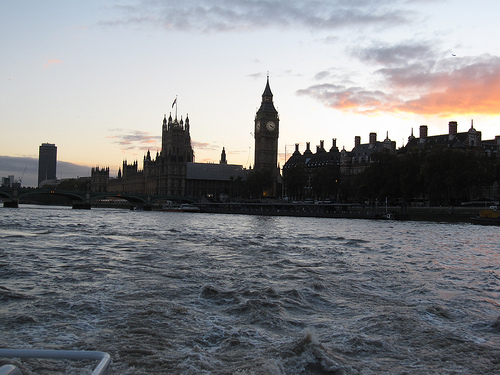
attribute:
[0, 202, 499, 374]
water — calm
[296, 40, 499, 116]
cloud — orange, fluffy, turning orange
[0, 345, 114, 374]
pipe — square, metal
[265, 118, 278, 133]
clock — large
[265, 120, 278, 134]
face — round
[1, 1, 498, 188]
sky — dull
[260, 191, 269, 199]
light — small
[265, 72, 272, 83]
tip — sharp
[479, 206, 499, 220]
sauce — orange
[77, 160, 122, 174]
sun — setting